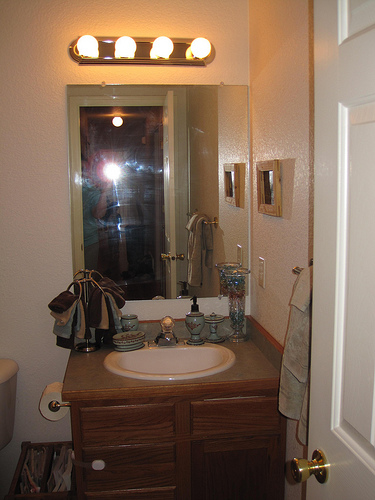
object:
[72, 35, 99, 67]
light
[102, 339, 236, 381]
sink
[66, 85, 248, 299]
mirror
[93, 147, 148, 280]
reflection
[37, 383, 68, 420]
toilet paper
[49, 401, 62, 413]
roll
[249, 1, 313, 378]
wall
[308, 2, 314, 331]
woodframe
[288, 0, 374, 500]
door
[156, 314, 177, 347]
faucet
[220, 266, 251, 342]
vase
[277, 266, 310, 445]
towel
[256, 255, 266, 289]
outlet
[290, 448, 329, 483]
knob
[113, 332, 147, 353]
soap dish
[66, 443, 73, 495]
magazines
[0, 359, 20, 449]
toliet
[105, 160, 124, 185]
flash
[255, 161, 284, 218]
picture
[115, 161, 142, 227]
shirt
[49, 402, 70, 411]
roll holder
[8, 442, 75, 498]
magazine rack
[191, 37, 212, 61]
light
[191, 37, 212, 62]
circle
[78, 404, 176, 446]
drawer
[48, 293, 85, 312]
towel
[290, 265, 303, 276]
towel hanger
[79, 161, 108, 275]
person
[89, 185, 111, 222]
arm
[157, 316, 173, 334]
handle